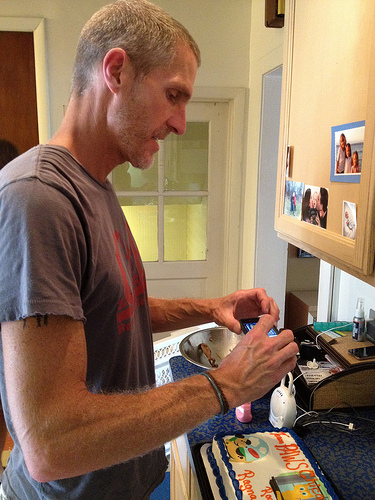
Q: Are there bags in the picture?
A: No, there are no bags.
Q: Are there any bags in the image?
A: No, there are no bags.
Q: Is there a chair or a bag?
A: No, there are no bags or chairs.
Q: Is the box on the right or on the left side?
A: The box is on the right of the image.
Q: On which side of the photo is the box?
A: The box is on the right of the image.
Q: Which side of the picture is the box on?
A: The box is on the right of the image.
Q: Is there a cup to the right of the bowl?
A: No, there is a box to the right of the bowl.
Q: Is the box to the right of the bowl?
A: Yes, the box is to the right of the bowl.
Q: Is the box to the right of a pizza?
A: No, the box is to the right of the bowl.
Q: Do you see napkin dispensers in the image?
A: No, there are no napkin dispensers.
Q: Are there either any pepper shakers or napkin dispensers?
A: No, there are no napkin dispensers or pepper shakers.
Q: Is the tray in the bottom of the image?
A: Yes, the tray is in the bottom of the image.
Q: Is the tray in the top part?
A: No, the tray is in the bottom of the image.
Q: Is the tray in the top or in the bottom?
A: The tray is in the bottom of the image.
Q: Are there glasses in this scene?
A: No, there are no glasses.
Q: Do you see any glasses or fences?
A: No, there are no glasses or fences.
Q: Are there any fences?
A: No, there are no fences.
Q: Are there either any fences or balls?
A: No, there are no fences or balls.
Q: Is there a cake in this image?
A: Yes, there is a cake.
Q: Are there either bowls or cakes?
A: Yes, there is a cake.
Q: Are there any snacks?
A: No, there are no snacks.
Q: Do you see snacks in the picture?
A: No, there are no snacks.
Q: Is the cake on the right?
A: Yes, the cake is on the right of the image.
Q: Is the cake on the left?
A: No, the cake is on the right of the image.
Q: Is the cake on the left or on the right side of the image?
A: The cake is on the right of the image.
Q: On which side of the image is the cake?
A: The cake is on the right of the image.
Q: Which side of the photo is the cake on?
A: The cake is on the right of the image.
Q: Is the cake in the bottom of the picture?
A: Yes, the cake is in the bottom of the image.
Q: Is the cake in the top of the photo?
A: No, the cake is in the bottom of the image.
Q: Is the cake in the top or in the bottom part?
A: The cake is in the bottom of the image.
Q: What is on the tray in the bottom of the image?
A: The cake is on the tray.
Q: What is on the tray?
A: The cake is on the tray.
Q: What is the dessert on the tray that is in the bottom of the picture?
A: The dessert is a cake.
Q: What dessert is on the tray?
A: The dessert is a cake.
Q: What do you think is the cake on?
A: The cake is on the tray.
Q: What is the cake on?
A: The cake is on the tray.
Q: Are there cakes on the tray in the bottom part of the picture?
A: Yes, there is a cake on the tray.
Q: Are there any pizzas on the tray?
A: No, there is a cake on the tray.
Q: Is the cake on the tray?
A: Yes, the cake is on the tray.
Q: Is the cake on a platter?
A: No, the cake is on the tray.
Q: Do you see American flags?
A: No, there are no American flags.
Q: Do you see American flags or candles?
A: No, there are no American flags or candles.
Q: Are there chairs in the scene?
A: No, there are no chairs.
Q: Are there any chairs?
A: No, there are no chairs.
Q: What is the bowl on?
A: The bowl is on the counter.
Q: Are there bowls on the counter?
A: Yes, there is a bowl on the counter.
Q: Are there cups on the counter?
A: No, there is a bowl on the counter.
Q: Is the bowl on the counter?
A: Yes, the bowl is on the counter.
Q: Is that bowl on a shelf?
A: No, the bowl is on the counter.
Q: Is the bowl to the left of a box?
A: Yes, the bowl is to the left of a box.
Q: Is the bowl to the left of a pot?
A: No, the bowl is to the left of a box.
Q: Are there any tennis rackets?
A: No, there are no tennis rackets.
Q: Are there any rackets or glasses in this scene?
A: No, there are no rackets or glasses.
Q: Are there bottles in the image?
A: Yes, there is a bottle.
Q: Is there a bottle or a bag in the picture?
A: Yes, there is a bottle.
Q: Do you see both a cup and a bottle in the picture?
A: No, there is a bottle but no cups.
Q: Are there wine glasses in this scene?
A: No, there are no wine glasses.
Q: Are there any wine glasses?
A: No, there are no wine glasses.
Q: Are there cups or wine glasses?
A: No, there are no wine glasses or cups.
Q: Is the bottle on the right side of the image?
A: Yes, the bottle is on the right of the image.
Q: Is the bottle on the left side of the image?
A: No, the bottle is on the right of the image.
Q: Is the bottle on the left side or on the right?
A: The bottle is on the right of the image.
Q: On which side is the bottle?
A: The bottle is on the right of the image.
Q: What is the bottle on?
A: The bottle is on the counter.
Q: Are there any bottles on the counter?
A: Yes, there is a bottle on the counter.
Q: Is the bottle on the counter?
A: Yes, the bottle is on the counter.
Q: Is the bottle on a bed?
A: No, the bottle is on the counter.